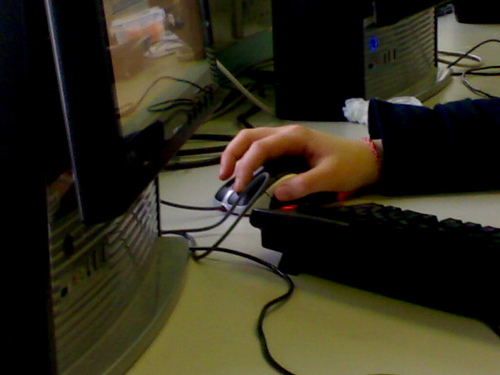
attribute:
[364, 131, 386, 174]
bracelet — pink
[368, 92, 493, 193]
sleeve — black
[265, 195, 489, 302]
keyboard — black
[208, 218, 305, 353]
cord — black